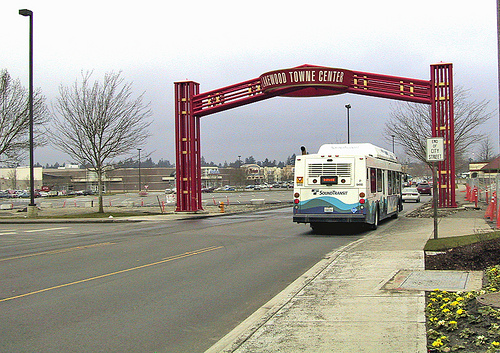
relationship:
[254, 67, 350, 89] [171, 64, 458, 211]
logo on gate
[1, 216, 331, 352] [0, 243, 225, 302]
road with yellow line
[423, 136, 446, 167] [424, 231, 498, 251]
sign stands on patch of grass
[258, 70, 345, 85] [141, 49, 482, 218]
words in center of archway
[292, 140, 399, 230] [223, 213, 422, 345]
bus parked next to sidewalk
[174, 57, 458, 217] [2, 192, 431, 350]
archway in road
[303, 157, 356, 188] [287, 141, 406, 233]
engine door on bus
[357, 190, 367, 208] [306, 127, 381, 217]
tail light on bus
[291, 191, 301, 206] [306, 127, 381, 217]
tail light on bus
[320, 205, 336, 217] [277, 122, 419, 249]
license plate on bus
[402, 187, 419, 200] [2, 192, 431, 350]
car on road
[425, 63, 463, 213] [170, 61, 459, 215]
red bars on archway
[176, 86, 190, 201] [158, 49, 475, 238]
decaorations on gate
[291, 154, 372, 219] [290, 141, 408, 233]
back of bus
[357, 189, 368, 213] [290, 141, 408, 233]
blinkers of bus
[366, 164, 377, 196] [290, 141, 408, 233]
window of bus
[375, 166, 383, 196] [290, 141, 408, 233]
window of bus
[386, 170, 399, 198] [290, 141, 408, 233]
window of bus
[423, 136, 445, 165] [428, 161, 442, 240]
sign on pole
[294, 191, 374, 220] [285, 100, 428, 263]
artwork on bus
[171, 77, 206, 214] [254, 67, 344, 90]
metal beside logo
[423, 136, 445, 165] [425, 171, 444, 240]
sign on pole